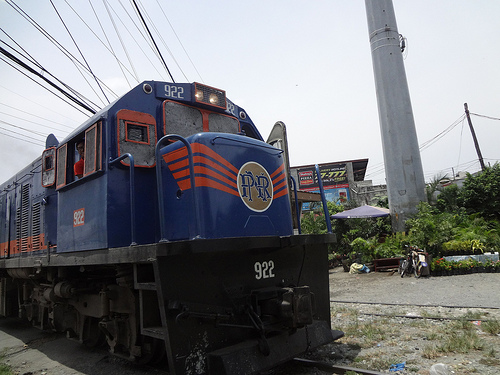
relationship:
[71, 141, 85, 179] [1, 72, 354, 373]
man inside train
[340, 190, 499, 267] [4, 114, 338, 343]
plants on side of train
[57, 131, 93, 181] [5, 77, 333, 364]
window of engine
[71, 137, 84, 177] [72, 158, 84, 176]
man in shirt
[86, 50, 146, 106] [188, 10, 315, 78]
white clouds in blue sky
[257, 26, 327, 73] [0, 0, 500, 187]
clouds in blue sky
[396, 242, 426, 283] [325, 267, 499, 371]
bicycle parked on sand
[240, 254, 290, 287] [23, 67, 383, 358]
922 painted on train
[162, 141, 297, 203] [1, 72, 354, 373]
lines on train